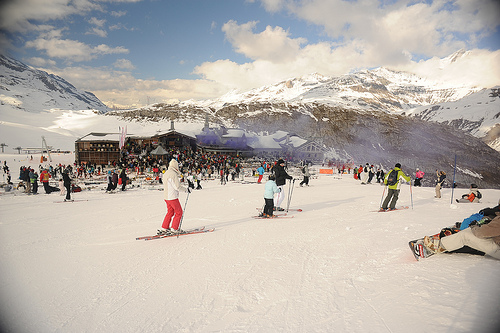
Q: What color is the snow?
A: White.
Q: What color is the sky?
A: Blue.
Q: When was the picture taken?
A: Daytime.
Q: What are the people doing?
A: Skiing and snowboarding.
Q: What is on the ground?
A: Snow.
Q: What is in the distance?
A: Mountains.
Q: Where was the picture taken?
A: Ski slopes.